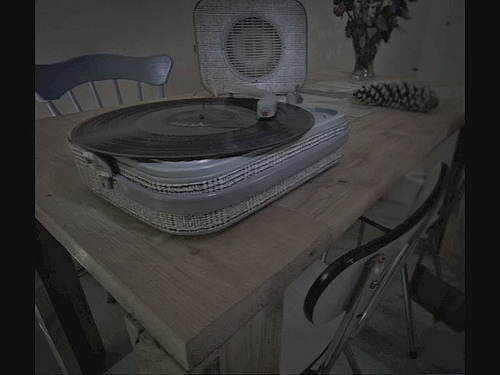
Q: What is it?
A: A record player.